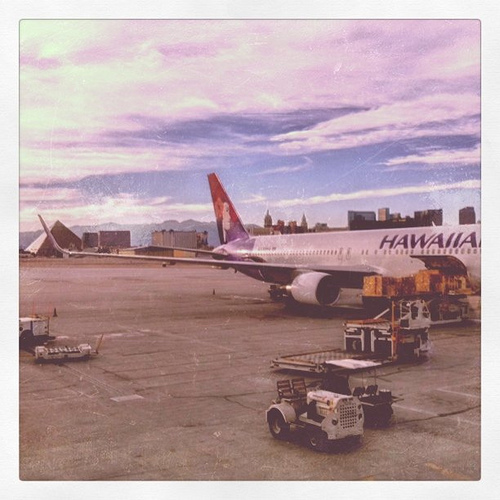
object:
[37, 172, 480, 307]
plane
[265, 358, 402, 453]
golf cart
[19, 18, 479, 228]
clouds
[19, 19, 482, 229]
sky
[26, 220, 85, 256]
pyramid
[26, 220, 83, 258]
background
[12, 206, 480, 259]
city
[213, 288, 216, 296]
cone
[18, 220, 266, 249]
mountain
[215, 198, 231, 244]
logo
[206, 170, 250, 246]
tail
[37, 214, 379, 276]
wing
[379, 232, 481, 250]
hawaii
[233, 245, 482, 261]
windows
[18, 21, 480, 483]
airport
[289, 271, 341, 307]
engine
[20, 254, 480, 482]
tarmac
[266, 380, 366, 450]
truck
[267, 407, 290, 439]
wheel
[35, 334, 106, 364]
trailer